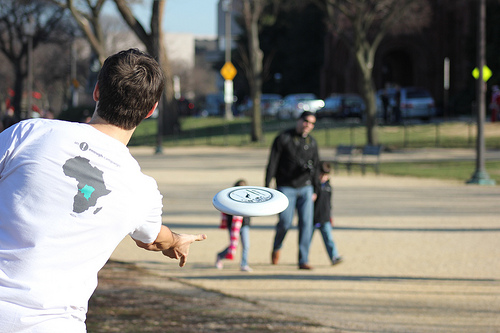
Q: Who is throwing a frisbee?
A: Man in white shirt.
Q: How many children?
A: Two.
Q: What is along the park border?
A: A black fence.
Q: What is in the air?
A: A white frisbee.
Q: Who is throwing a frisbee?
A: Person wearing a white shirt.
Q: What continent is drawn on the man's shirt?
A: Africa.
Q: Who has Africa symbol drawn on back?
A: Man in white t-shirt.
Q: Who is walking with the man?
A: Children.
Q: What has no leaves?
A: Trees.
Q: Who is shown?
A: Man and children.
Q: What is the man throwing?
A: Frisbee.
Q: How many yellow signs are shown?
A: Two.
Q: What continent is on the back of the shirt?
A: Africa.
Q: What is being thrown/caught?
A: Frisbee.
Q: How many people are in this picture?
A: Four.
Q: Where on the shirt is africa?
A: Back.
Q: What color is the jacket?
A: Black.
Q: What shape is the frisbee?
A: Circle.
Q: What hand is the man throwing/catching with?
A: Right.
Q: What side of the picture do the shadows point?
A: Left.